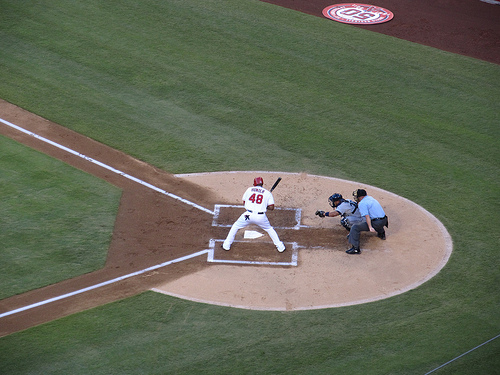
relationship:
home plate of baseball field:
[241, 226, 265, 244] [2, 2, 499, 374]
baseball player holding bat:
[217, 172, 289, 254] [269, 178, 282, 194]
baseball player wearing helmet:
[217, 172, 289, 254] [252, 176, 265, 187]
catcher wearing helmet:
[312, 194, 365, 234] [327, 193, 342, 208]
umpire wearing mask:
[346, 188, 391, 256] [351, 187, 361, 207]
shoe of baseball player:
[220, 242, 231, 254] [217, 172, 289, 254]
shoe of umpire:
[344, 244, 362, 256] [346, 188, 391, 256]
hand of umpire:
[368, 226, 377, 235] [346, 188, 391, 256]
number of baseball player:
[247, 192, 266, 206] [217, 172, 289, 254]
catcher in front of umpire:
[312, 194, 365, 234] [346, 188, 391, 256]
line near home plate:
[1, 118, 215, 216] [241, 226, 265, 244]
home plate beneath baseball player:
[241, 226, 265, 244] [217, 172, 289, 254]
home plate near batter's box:
[241, 226, 265, 244] [206, 236, 299, 268]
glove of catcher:
[315, 208, 330, 219] [312, 194, 365, 234]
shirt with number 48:
[240, 185, 275, 214] [247, 190, 265, 207]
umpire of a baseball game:
[346, 188, 391, 256] [7, 8, 484, 368]